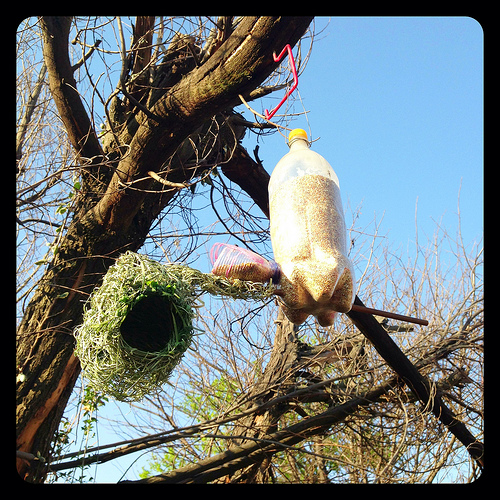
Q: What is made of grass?
A: The net.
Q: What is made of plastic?
A: The bottle.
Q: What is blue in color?
A: The sky.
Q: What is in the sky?
A: Nothing.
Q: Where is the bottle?
A: In the tree.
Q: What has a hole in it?
A: The structure.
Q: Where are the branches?
A: On the tree.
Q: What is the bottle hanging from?
A: Branch.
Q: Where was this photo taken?
A: Outside near a bird's nest.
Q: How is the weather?
A: Clear and sunny.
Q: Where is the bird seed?
A: In a plastic bottle.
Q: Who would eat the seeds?
A: Birds.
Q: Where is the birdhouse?
A: Hanging in the tree.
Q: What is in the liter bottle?
A: Bird seed.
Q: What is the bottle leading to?
A: Bird nest.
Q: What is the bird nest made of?
A: Straw and grass.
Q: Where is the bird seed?
A: Liter bottle.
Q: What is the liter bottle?
A: Homemade bird feeder.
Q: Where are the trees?
A: In the air.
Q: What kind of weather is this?
A: Sunny, clear , with no clouds.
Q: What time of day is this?
A: Daylight hours.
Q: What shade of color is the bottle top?
A: Yellow.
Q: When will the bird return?
A: To eat or sleep.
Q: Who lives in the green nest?
A: A bird.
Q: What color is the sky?
A: Blue.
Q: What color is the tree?
A: Brown.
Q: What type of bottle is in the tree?
A: Soda.